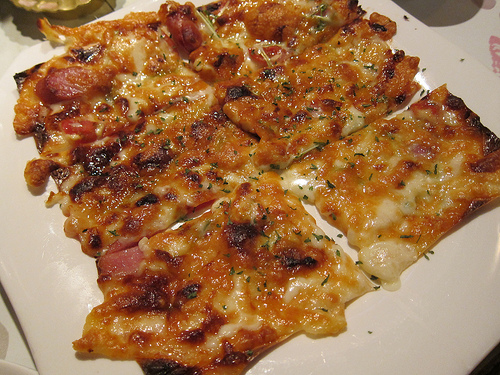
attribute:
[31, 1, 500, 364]
cheese — toasted, hanging, topping, pizza topping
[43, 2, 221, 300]
ham — red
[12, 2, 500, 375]
crust — thin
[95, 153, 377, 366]
slice — rectangle, pizza, square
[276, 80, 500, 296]
slice — rectangle, pizza, square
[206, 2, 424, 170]
slice — rectangle, pizza, square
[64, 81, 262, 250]
piece — food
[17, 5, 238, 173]
piece — food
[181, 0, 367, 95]
piece — food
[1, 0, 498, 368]
surface — white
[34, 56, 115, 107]
piece — red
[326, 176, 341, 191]
piece — green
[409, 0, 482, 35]
shadow — cast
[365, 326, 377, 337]
dot — small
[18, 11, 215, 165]
corner — tasty, black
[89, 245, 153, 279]
ham — sliced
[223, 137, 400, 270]
herbs — green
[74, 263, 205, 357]
cheese — burned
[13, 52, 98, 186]
border — black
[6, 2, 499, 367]
pizza — sliced, white, rectangle, greasy, deep, cut, neat, restaurant's, tasty, cooked, cheese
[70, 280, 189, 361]
piece — sticking out